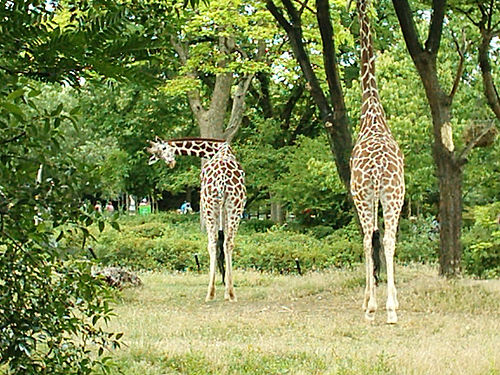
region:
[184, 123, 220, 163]
long neck of giraffe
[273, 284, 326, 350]
light green grass on ground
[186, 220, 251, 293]
legs of the giraffe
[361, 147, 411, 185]
spots on the giraffe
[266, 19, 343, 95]
branches on a tree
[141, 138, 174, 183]
head of a giraffe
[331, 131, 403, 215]
back of the giraffe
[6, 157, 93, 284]
leaves on a tree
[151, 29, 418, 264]
two giraffes in the grass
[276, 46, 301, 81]
sky behind the trees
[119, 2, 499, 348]
two giraffes standing together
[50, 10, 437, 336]
two giraffes standing next to each other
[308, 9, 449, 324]
one tall giraffes standing up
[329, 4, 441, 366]
one tall giraffe in the grass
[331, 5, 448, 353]
one giraffe standing in grass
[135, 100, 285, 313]
a giraffe with his neck bent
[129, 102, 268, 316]
a giraffe looking behind him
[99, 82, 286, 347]
a giraffe standing on the grass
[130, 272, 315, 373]
a green grass field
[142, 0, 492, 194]
trees with green leaves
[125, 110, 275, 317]
one giraffe looking backwards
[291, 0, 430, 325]
one giraffe looking up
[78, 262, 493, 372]
brown and green grass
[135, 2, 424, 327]
brown and white giraffes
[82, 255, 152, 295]
one rock in the grass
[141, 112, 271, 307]
giraffe cranes its neck left and back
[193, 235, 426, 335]
no spots on the legs of the giraffes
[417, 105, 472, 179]
light patch on the tree trunk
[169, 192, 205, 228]
someone in the background wears blue shirt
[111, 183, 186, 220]
athletic field in the background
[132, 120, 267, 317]
The giraffe is looking behind.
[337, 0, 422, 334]
This giraffe is too tall for the picture.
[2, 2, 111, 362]
Lots of plants to the left.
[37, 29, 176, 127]
The leaves are green.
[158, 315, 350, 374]
The grass is green but dry.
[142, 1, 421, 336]
Two giraffes are standing.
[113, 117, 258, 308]
The giraffe is brown and white.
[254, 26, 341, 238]
A lot of trees are in the background.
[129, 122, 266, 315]
The giraffe has its head low.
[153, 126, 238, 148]
The giraffe has a brown mane.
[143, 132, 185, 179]
the head of a giraffe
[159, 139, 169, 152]
the eye of a giraffe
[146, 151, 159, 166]
the ear of a giraffe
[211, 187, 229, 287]
the tail of a giraffe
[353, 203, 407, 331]
the legs of a giraffe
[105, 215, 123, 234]
a green leaf on the tree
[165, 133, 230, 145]
the mane of the giraffe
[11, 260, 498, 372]
a grassy green and yellow field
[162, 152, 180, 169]
the nose of the giraffe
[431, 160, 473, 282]
a brown tree trunk